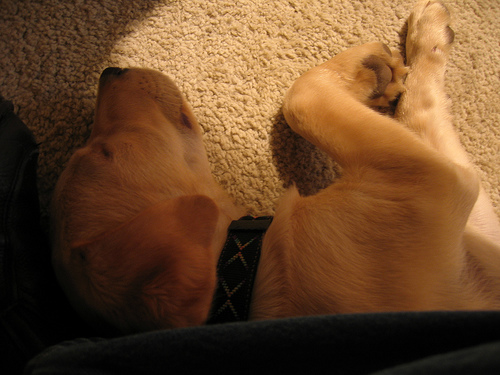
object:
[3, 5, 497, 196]
floor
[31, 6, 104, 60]
shadow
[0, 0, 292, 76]
ground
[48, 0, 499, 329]
dog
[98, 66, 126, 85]
nose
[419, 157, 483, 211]
elbow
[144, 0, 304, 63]
carpet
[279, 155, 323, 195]
shadow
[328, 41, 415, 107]
dog's paw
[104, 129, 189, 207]
dog's face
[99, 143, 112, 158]
eye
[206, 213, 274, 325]
collar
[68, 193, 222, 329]
ear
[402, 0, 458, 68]
paw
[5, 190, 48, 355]
shadow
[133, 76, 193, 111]
whiskers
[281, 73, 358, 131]
elbow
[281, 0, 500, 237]
legs